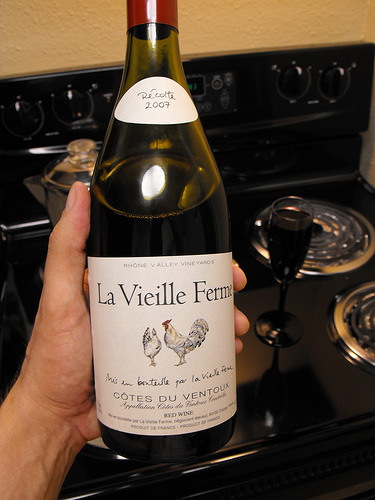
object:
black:
[118, 283, 123, 288]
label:
[113, 77, 199, 126]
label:
[86, 251, 237, 434]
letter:
[97, 283, 107, 305]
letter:
[106, 289, 116, 306]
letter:
[117, 283, 139, 306]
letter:
[193, 280, 206, 304]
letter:
[176, 291, 187, 305]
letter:
[143, 292, 155, 307]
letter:
[213, 287, 220, 301]